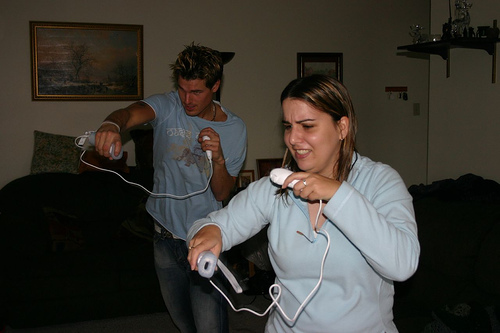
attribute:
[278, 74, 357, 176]
girl/brown hair — brown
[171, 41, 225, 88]
hair — brown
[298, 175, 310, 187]
ring — silver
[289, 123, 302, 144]
nose — woman's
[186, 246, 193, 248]
ring — gold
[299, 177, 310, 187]
ring — silver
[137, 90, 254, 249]
tee shirt — blue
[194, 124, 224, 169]
controller — game